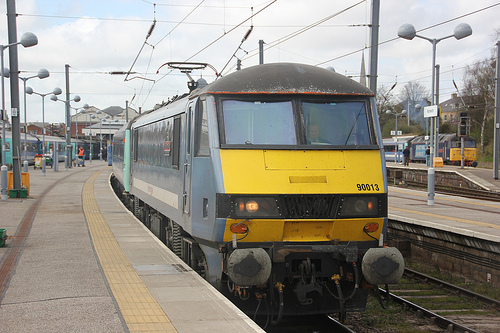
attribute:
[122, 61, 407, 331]
train — parked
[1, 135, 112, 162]
train — blue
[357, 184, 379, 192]
number — black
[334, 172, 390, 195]
numbers — black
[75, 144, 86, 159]
sweater — Black 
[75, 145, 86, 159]
vest — Orange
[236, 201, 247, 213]
light — orange 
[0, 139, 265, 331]
sidewalk — yellow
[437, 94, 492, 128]
brick building — red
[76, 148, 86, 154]
jacket — orange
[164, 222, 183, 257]
wheel — black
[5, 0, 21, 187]
pole — metal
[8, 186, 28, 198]
base — green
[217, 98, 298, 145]
window — square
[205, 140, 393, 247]
front — yellow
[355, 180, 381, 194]
number — black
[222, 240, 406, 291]
brakes — round, metal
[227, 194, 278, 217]
headlight — working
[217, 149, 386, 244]
paint — yellow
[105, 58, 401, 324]
train — yellow, blue